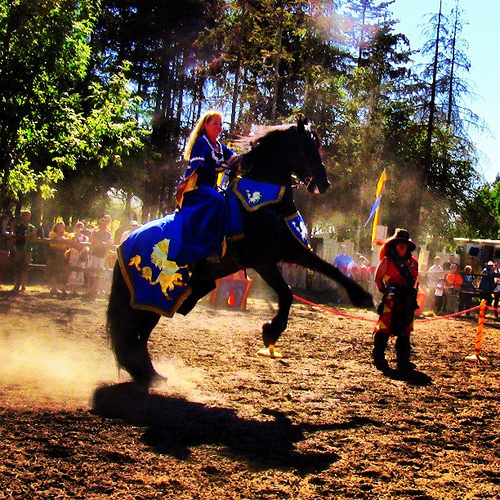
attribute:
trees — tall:
[18, 11, 483, 331]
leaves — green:
[3, 0, 150, 206]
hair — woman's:
[181, 110, 226, 161]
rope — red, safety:
[231, 258, 498, 370]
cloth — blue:
[102, 193, 206, 317]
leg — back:
[125, 312, 177, 383]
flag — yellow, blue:
[364, 167, 386, 227]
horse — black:
[84, 115, 380, 405]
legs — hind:
[86, 267, 183, 409]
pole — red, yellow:
[473, 292, 491, 352]